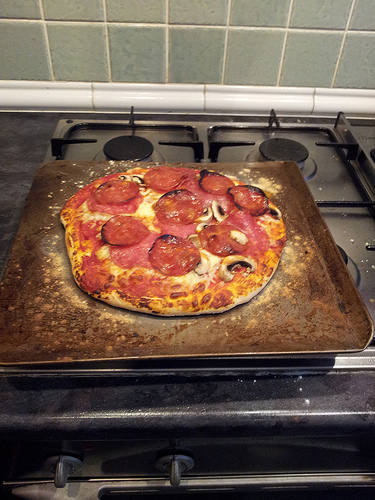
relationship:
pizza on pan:
[61, 165, 286, 316] [0, 160, 374, 375]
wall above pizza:
[2, 3, 373, 113] [61, 165, 286, 316]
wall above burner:
[2, 3, 373, 113] [48, 96, 208, 164]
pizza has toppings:
[61, 165, 286, 316] [93, 168, 270, 275]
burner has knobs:
[207, 108, 374, 213] [39, 453, 195, 487]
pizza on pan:
[61, 165, 286, 316] [0, 160, 374, 367]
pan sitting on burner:
[0, 160, 374, 367] [207, 108, 374, 213]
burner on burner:
[207, 108, 374, 206] [207, 108, 374, 213]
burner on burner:
[48, 105, 203, 162] [207, 108, 374, 213]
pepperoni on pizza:
[148, 233, 201, 275] [61, 165, 286, 316]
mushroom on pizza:
[217, 254, 255, 280] [61, 165, 286, 316]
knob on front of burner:
[158, 454, 192, 486] [207, 108, 374, 213]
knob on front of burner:
[46, 455, 80, 487] [207, 108, 374, 213]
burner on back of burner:
[207, 108, 374, 206] [207, 108, 374, 213]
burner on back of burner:
[48, 105, 203, 162] [207, 108, 374, 213]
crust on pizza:
[59, 167, 286, 315] [61, 165, 286, 316]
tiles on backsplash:
[0, 1, 374, 119] [0, 0, 375, 122]